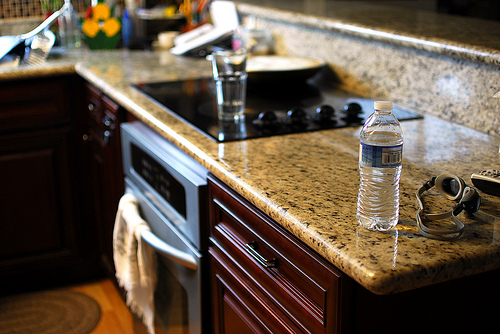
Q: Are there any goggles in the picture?
A: Yes, there are goggles.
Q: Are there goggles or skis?
A: Yes, there are goggles.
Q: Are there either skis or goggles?
A: Yes, there are goggles.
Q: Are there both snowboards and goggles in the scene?
A: No, there are goggles but no snowboards.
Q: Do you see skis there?
A: No, there are no skis.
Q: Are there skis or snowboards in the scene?
A: No, there are no skis or snowboards.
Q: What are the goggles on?
A: The goggles are on the counter.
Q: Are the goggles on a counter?
A: Yes, the goggles are on a counter.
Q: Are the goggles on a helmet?
A: No, the goggles are on a counter.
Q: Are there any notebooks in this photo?
A: No, there are no notebooks.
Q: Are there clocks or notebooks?
A: No, there are no notebooks or clocks.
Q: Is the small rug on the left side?
A: Yes, the rug is on the left of the image.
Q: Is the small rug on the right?
A: No, the rug is on the left of the image.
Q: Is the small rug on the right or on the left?
A: The rug is on the left of the image.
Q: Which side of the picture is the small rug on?
A: The rug is on the left of the image.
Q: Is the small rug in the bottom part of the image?
A: Yes, the rug is in the bottom of the image.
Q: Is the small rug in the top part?
A: No, the rug is in the bottom of the image.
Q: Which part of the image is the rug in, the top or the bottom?
A: The rug is in the bottom of the image.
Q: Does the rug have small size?
A: Yes, the rug is small.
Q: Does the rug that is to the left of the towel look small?
A: Yes, the rug is small.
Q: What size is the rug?
A: The rug is small.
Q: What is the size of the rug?
A: The rug is small.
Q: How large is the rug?
A: The rug is small.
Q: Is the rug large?
A: No, the rug is small.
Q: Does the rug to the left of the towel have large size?
A: No, the rug is small.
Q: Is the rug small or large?
A: The rug is small.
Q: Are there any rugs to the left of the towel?
A: Yes, there is a rug to the left of the towel.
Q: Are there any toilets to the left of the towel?
A: No, there is a rug to the left of the towel.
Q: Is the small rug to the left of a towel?
A: Yes, the rug is to the left of a towel.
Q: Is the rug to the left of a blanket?
A: No, the rug is to the left of a towel.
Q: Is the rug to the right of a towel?
A: No, the rug is to the left of a towel.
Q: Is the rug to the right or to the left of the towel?
A: The rug is to the left of the towel.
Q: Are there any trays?
A: No, there are no trays.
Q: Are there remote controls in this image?
A: Yes, there is a remote control.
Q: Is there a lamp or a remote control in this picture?
A: Yes, there is a remote control.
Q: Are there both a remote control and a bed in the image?
A: No, there is a remote control but no beds.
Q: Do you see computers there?
A: No, there are no computers.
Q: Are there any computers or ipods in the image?
A: No, there are no computers or ipods.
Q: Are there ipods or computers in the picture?
A: No, there are no computers or ipods.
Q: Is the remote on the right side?
A: Yes, the remote is on the right of the image.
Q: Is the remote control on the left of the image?
A: No, the remote control is on the right of the image.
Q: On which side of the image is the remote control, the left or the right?
A: The remote control is on the right of the image.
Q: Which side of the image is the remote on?
A: The remote is on the right of the image.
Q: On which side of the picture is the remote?
A: The remote is on the right of the image.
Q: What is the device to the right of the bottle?
A: The device is a remote control.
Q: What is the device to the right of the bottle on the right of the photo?
A: The device is a remote control.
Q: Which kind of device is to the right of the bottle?
A: The device is a remote control.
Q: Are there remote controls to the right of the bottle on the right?
A: Yes, there is a remote control to the right of the bottle.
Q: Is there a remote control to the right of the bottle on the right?
A: Yes, there is a remote control to the right of the bottle.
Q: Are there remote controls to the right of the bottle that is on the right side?
A: Yes, there is a remote control to the right of the bottle.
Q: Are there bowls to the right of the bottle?
A: No, there is a remote control to the right of the bottle.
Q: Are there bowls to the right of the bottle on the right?
A: No, there is a remote control to the right of the bottle.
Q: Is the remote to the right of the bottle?
A: Yes, the remote is to the right of the bottle.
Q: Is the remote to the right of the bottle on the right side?
A: Yes, the remote is to the right of the bottle.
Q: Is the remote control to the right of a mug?
A: No, the remote control is to the right of the bottle.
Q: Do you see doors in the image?
A: Yes, there is a door.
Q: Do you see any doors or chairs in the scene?
A: Yes, there is a door.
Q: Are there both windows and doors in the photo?
A: No, there is a door but no windows.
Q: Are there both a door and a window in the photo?
A: No, there is a door but no windows.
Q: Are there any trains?
A: No, there are no trains.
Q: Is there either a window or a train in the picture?
A: No, there are no trains or windows.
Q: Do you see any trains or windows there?
A: No, there are no trains or windows.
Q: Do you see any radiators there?
A: No, there are no radiators.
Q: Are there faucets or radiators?
A: No, there are no radiators or faucets.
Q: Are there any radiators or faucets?
A: No, there are no radiators or faucets.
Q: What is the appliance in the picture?
A: The appliance is a stove.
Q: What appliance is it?
A: The appliance is a stove.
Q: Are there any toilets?
A: No, there are no toilets.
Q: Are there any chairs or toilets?
A: No, there are no toilets or chairs.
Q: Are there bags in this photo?
A: No, there are no bags.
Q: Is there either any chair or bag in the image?
A: No, there are no bags or chairs.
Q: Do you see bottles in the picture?
A: Yes, there is a bottle.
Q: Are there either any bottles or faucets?
A: Yes, there is a bottle.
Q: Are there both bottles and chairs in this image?
A: No, there is a bottle but no chairs.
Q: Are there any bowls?
A: No, there are no bowls.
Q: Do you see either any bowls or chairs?
A: No, there are no bowls or chairs.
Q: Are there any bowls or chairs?
A: No, there are no bowls or chairs.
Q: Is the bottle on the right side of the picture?
A: Yes, the bottle is on the right of the image.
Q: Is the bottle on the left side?
A: No, the bottle is on the right of the image.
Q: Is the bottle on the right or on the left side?
A: The bottle is on the right of the image.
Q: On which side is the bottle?
A: The bottle is on the right of the image.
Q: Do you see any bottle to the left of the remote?
A: Yes, there is a bottle to the left of the remote.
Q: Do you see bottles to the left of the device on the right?
A: Yes, there is a bottle to the left of the remote.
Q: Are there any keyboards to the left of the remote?
A: No, there is a bottle to the left of the remote.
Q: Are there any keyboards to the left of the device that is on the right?
A: No, there is a bottle to the left of the remote.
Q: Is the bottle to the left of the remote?
A: Yes, the bottle is to the left of the remote.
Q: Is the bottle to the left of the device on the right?
A: Yes, the bottle is to the left of the remote.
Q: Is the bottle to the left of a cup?
A: No, the bottle is to the left of the remote.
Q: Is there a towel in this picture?
A: Yes, there is a towel.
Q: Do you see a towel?
A: Yes, there is a towel.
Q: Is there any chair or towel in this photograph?
A: Yes, there is a towel.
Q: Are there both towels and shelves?
A: No, there is a towel but no shelves.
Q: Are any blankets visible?
A: No, there are no blankets.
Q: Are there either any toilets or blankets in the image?
A: No, there are no blankets or toilets.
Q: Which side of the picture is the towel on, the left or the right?
A: The towel is on the left of the image.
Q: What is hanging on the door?
A: The towel is hanging on the door.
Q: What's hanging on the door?
A: The towel is hanging on the door.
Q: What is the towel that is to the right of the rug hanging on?
A: The towel is hanging on the door.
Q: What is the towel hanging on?
A: The towel is hanging on the door.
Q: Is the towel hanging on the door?
A: Yes, the towel is hanging on the door.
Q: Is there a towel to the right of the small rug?
A: Yes, there is a towel to the right of the rug.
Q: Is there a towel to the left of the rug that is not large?
A: No, the towel is to the right of the rug.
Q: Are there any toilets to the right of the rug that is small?
A: No, there is a towel to the right of the rug.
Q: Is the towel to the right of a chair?
A: No, the towel is to the right of a rug.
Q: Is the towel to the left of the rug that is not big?
A: No, the towel is to the right of the rug.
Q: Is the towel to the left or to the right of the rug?
A: The towel is to the right of the rug.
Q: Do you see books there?
A: No, there are no books.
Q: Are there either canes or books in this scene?
A: No, there are no books or canes.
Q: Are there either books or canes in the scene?
A: No, there are no books or canes.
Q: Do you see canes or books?
A: No, there are no books or canes.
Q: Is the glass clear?
A: Yes, the glass is clear.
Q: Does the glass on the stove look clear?
A: Yes, the glass is clear.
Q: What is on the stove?
A: The glass is on the stove.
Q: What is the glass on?
A: The glass is on the stove.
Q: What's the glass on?
A: The glass is on the stove.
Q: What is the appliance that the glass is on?
A: The appliance is a stove.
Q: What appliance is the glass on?
A: The glass is on the stove.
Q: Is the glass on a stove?
A: Yes, the glass is on a stove.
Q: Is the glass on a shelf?
A: No, the glass is on a stove.